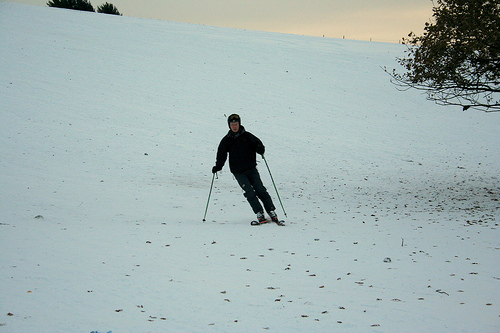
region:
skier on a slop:
[203, 97, 296, 237]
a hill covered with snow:
[10, 5, 492, 325]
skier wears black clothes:
[204, 107, 291, 229]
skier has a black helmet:
[201, 103, 292, 235]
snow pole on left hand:
[252, 141, 294, 220]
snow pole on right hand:
[191, 160, 229, 222]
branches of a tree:
[393, 2, 499, 135]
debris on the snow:
[318, 144, 498, 329]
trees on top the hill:
[11, 0, 154, 30]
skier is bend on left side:
[196, 107, 301, 238]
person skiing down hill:
[214, 109, 316, 219]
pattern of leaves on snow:
[213, 245, 305, 299]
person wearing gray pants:
[218, 112, 273, 218]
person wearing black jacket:
[215, 120, 257, 182]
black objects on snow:
[330, 147, 436, 208]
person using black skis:
[242, 212, 323, 250]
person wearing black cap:
[225, 110, 243, 117]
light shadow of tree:
[385, 185, 461, 230]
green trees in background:
[72, 3, 130, 16]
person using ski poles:
[204, 184, 243, 229]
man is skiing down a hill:
[202, 113, 287, 226]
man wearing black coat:
[215, 125, 264, 175]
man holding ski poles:
[202, 153, 288, 223]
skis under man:
[249, 217, 284, 227]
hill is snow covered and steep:
[0, 0, 498, 331]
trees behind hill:
[46, 0, 121, 16]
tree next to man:
[380, 0, 498, 113]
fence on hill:
[322, 34, 401, 44]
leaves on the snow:
[2, 108, 499, 331]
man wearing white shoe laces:
[255, 210, 275, 219]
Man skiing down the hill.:
[211, 108, 300, 257]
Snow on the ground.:
[22, 35, 147, 331]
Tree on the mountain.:
[382, 3, 498, 153]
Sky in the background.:
[145, 0, 460, 49]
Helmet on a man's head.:
[199, 93, 271, 143]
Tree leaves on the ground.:
[331, 150, 491, 227]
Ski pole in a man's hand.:
[194, 154, 228, 236]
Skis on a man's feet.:
[241, 202, 290, 234]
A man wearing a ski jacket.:
[199, 107, 274, 180]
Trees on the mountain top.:
[42, 1, 132, 18]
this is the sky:
[303, 4, 373, 35]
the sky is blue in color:
[340, 0, 355, 15]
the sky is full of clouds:
[341, 9, 405, 41]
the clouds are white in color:
[323, 7, 395, 32]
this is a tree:
[388, 2, 499, 104]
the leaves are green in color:
[424, 37, 460, 69]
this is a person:
[183, 107, 310, 222]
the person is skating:
[186, 95, 306, 226]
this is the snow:
[21, 235, 107, 305]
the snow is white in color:
[41, 245, 72, 256]